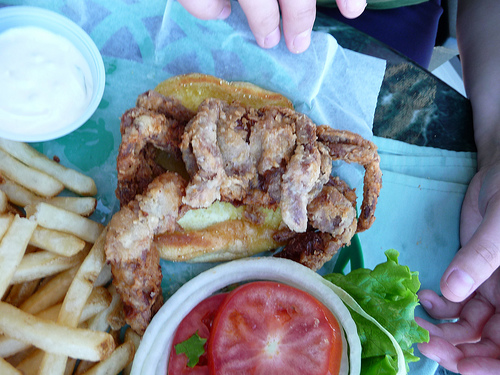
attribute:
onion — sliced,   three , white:
[125, 253, 369, 375]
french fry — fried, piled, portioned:
[41, 221, 110, 375]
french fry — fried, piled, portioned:
[28, 199, 107, 245]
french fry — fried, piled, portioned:
[23, 224, 90, 258]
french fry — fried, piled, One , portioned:
[1, 177, 103, 219]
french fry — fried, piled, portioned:
[1, 297, 116, 365]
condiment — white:
[0, 26, 96, 134]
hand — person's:
[173, 0, 371, 56]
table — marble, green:
[3, 3, 486, 373]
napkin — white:
[308, 133, 480, 375]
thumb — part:
[434, 193, 499, 304]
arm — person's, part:
[450, 1, 499, 176]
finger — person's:
[413, 288, 462, 320]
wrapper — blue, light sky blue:
[3, 1, 390, 298]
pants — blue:
[314, 3, 442, 84]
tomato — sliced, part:
[218, 281, 339, 373]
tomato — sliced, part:
[176, 294, 213, 372]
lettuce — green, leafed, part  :
[333, 270, 428, 341]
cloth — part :
[231, 44, 370, 111]